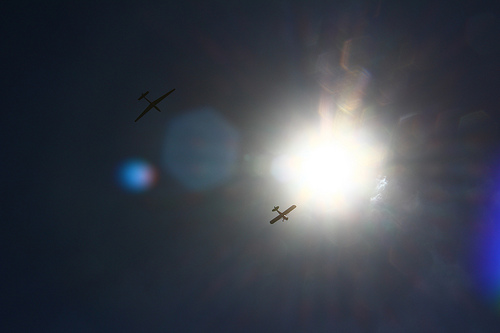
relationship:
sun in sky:
[259, 112, 397, 217] [11, 9, 498, 330]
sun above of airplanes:
[259, 112, 397, 217] [128, 86, 300, 235]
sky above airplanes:
[11, 9, 498, 330] [128, 86, 300, 235]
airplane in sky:
[133, 82, 178, 124] [11, 9, 498, 330]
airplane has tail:
[133, 82, 178, 124] [136, 88, 150, 101]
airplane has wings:
[133, 82, 178, 124] [153, 91, 178, 104]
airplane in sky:
[266, 203, 300, 230] [11, 9, 498, 330]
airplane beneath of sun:
[266, 203, 300, 230] [259, 112, 397, 217]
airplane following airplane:
[133, 82, 178, 124] [266, 203, 300, 230]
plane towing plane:
[133, 82, 178, 124] [266, 203, 300, 230]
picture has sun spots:
[11, 9, 498, 330] [109, 111, 303, 193]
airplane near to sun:
[266, 203, 300, 230] [259, 112, 397, 217]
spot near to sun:
[159, 105, 244, 194] [259, 112, 397, 217]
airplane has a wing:
[133, 82, 178, 124] [129, 107, 155, 123]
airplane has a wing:
[133, 82, 178, 124] [155, 88, 180, 106]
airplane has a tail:
[133, 82, 178, 124] [136, 88, 150, 101]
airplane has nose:
[133, 82, 178, 124] [154, 105, 161, 115]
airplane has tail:
[266, 203, 300, 230] [268, 205, 284, 215]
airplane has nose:
[266, 203, 300, 230] [282, 216, 290, 224]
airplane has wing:
[266, 203, 300, 230] [284, 206, 299, 215]